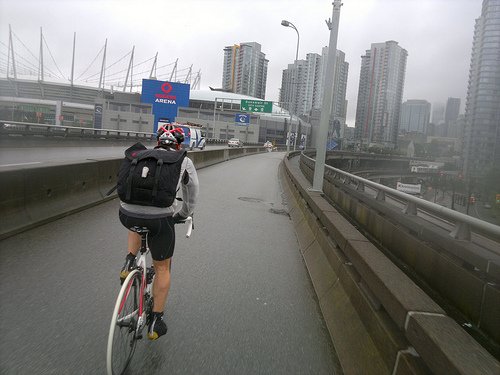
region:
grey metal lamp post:
[316, 2, 343, 193]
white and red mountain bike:
[103, 210, 195, 371]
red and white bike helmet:
[156, 125, 183, 142]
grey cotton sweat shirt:
[120, 155, 199, 220]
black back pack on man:
[119, 147, 185, 207]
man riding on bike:
[106, 124, 198, 374]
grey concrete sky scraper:
[357, 41, 407, 145]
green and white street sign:
[241, 99, 273, 112]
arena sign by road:
[141, 80, 189, 131]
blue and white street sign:
[236, 113, 248, 123]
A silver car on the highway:
[220, 130, 247, 150]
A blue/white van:
[160, 115, 205, 150]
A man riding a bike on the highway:
[65, 105, 225, 370]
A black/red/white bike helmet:
[150, 115, 185, 150]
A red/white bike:
[85, 205, 195, 370]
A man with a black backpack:
[80, 110, 220, 340]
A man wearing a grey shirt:
[75, 115, 225, 335]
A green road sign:
[235, 91, 275, 111]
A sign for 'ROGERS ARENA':
[130, 70, 190, 135]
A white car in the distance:
[256, 131, 276, 151]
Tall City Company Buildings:
[222, 44, 404, 146]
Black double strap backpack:
[115, 141, 186, 208]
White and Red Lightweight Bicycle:
[97, 202, 194, 374]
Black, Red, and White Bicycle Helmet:
[154, 124, 186, 147]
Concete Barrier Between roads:
[0, 140, 309, 241]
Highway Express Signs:
[215, 99, 281, 144]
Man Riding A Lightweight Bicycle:
[99, 117, 204, 374]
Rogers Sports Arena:
[0, 32, 304, 146]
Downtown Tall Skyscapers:
[215, 30, 498, 188]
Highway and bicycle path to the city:
[0, 88, 499, 372]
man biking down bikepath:
[13, 114, 318, 374]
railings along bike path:
[283, 138, 499, 363]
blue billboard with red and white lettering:
[140, 80, 190, 130]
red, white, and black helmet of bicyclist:
[153, 122, 187, 143]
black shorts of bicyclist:
[113, 216, 178, 260]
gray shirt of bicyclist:
[118, 154, 200, 221]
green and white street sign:
[238, 96, 274, 120]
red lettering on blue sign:
[151, 90, 178, 99]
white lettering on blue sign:
[155, 98, 185, 106]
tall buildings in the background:
[216, 31, 404, 162]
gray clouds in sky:
[4, 2, 476, 83]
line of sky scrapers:
[221, 40, 409, 154]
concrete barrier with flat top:
[282, 145, 499, 365]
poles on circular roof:
[3, 25, 110, 126]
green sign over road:
[212, 97, 295, 149]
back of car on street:
[217, 136, 244, 153]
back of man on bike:
[104, 123, 201, 373]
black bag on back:
[115, 124, 199, 229]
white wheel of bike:
[104, 268, 146, 372]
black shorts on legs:
[117, 209, 175, 311]